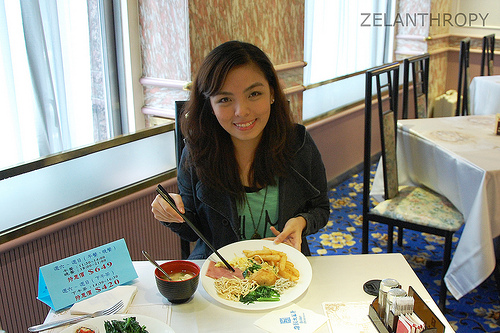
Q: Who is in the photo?
A: A girl.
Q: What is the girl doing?
A: Sitting.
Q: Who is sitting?
A: A girl.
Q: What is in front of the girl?
A: A plate.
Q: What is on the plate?
A: Food.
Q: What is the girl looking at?
A: Camera.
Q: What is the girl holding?
A: Plate.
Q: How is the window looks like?
A: Closed.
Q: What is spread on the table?
A: Tablecloth.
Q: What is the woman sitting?
A: Table.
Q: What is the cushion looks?
A: Stuffed.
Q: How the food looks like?
A: Yummy.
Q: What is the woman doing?
A: Eating.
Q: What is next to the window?
A: White table.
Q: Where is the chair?
A: At a nearby table.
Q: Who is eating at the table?
A: A woman.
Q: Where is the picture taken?
A: Restaurant.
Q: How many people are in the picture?
A: One.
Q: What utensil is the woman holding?
A: Chopsticks.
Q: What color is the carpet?
A: Blue.